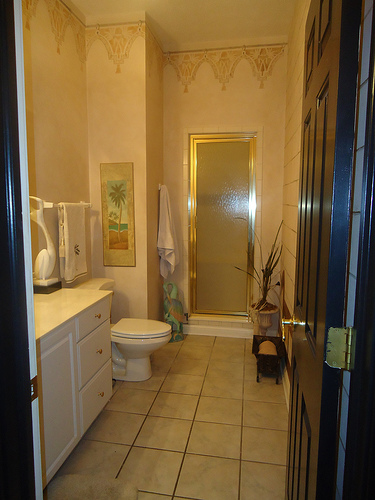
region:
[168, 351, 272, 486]
Light brown tiled floor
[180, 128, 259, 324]
Frosted shower door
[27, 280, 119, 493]
White bathroom cabinets with white counter top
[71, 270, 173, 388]
White ceramic toilet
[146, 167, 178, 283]
White towel hanging on a wall hook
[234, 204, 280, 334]
Potted plant in the corner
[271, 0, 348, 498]
Dark brown painted bathroom door that's open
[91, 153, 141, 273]
Wall hanging with palm tree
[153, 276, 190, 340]
Small sculpture on the corner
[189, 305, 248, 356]
Step up into shower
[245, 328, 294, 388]
wooden towel holder in bathroom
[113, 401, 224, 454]
cream colored tile on bathroom floor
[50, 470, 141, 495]
fuzzy white bathroom rug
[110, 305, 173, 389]
elongated white toilet seat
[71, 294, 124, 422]
trio of white drawers on bathroom vanity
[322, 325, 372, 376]
hinges on a bathroom door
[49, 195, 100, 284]
towel on a bar over the toilet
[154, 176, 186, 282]
white towel on hook near shower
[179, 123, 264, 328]
gold trimmed shower door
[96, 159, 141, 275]
picture of palm tree in the desert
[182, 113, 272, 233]
Gold trim around shower door.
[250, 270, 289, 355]
Large plant in pot in corner.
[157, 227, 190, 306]
Towel hanging on wall near shower.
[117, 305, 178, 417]
White toilet in bathroom.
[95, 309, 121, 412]
Gold handles on drawers.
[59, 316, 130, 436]
Drawers in cabinet are white.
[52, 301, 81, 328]
White counter top on vanity.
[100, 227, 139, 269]
Picture on wall near toilet.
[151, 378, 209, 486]
White tiles on bathroom floor.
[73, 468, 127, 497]
White bath mat on floor in bathroom.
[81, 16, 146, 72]
a gold border on a bathroom wall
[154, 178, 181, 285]
a towel hanging on a wall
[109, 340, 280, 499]
an off-white tile floor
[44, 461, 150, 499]
a rug in front of a bathroom counter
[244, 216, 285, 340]
a plant in the corner of a bathroom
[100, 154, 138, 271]
a picture of a palm tree on the wall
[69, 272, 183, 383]
a white toilet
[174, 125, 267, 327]
a gold edged shower door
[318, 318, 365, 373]
the hinge on a bathroom door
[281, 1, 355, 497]
a black bathroom door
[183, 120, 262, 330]
big mirror on a bathroom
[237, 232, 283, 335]
pot with a plant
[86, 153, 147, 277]
a picture on a wall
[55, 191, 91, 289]
towel is white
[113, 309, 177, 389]
toilet is cover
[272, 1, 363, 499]
brown door is open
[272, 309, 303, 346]
handle of door is silver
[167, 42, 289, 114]
decorations on the wall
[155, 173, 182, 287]
a towel hangs near the mirror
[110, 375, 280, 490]
tiles on the floor